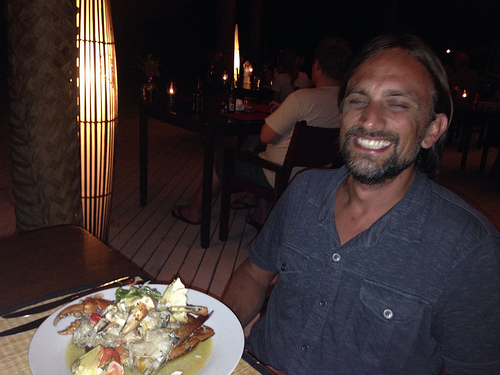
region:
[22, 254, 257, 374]
Food is in the plate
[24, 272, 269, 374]
The plate is white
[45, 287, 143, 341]
Crab for dinner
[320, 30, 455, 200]
The man is smiling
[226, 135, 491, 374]
His shirt is blue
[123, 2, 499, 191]
Various people in the back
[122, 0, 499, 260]
The room is dim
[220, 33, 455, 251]
The man is Caucasian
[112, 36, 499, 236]
The tables are made of wood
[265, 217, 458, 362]
He has pockets on his shirt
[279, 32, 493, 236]
Man who is smiling.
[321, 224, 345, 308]
Buttons on the shirt.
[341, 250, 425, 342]
Pocket on the shirt.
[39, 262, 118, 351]
Plate with food on it.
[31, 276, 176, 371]
Food on the plate.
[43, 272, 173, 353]
Claw on the crab.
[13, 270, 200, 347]
Silverware on the table.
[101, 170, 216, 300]
Slats on the deck.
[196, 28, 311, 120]
Light in the background.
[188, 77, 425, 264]
Man sitting in a chair.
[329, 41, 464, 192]
man is smiling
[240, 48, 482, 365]
man wearing blue short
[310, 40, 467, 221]
man has facial hair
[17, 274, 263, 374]
seafood entree on table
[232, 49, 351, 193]
man sitting on dark chair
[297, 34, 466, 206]
man with white large teeth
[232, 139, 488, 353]
man wearing short sleeves shirt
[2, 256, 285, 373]
yellow and white checkered tabletop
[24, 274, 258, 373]
entree with yellow sauce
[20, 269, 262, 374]
large round white plate with food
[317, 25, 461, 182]
The man is smiling.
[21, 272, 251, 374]
A lobster meal on a plate.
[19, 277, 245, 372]
The plate is white.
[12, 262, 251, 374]
The plate is round.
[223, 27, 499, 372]
The man is wearing a shirt.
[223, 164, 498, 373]
The shirt is blue.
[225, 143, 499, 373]
The shirt has pockets.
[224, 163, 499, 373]
The shirt has sleeves.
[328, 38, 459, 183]
Man's teeth are white.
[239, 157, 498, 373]
The shirt has buttons.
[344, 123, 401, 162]
Man is smiling in the foreground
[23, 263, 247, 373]
Seafood is on a plate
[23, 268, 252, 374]
The plate is white in color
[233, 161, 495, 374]
Man is wearing a blue shirt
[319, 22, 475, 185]
Man has long hair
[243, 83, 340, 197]
Person in the background is wearing a shirt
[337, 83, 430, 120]
Man's eyes are closed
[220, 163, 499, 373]
Man is wearing a button up shirt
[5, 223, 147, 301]
Table is made of wood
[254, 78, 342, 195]
Man is wearing a white tshirt